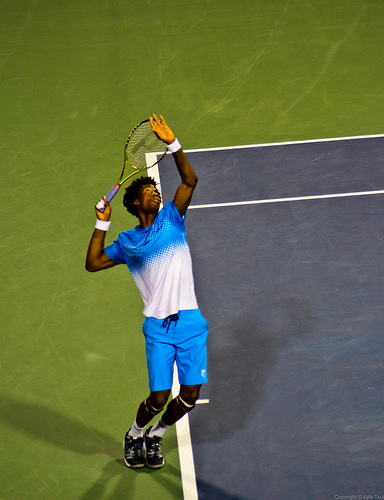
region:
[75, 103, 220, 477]
tennis player getting ready to serve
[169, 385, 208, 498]
white line discerning edge of tennis court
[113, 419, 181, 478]
tennis players feet with shoes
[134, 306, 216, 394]
tennis player with blue short on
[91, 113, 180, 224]
tennis racket getting ready to serve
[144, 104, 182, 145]
left hand of tennis player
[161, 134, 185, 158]
white wrist band on left arm of tennis player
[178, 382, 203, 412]
left knee of tennis player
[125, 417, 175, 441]
white socks of tennis player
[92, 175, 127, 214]
blue handle of tennis racket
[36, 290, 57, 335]
scuff marks on green tennis court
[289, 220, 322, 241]
scuff marks on blue tennis court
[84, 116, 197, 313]
man in blue and white shirt swinging racket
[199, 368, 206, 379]
white symbol on blue shorts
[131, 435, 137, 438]
yellow symbol on black shoes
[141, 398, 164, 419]
man wearing yellow and black knee pads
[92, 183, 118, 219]
man holding racket with blue handle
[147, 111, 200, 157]
tennis player wearing white sweatband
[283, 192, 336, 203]
white line on blue tennis court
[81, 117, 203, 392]
man in blue shorts swinging racket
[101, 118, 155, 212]
racquet held in right hand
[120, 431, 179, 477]
feet are together on court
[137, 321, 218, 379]
person wearing blue shorts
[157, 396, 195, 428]
sock is black and gold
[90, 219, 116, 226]
white wrist band on right wrist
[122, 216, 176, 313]
person wearing blue and white shirt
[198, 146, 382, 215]
white lines on the court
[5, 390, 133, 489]
shadow on the ground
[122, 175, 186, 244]
person looking up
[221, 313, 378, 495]
court is made of clay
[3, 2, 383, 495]
surface of tennis court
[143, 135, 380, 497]
blue section of court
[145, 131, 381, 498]
white lines on court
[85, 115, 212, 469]
tennis player on court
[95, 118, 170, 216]
racket in player's hand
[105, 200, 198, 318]
blue and white shirt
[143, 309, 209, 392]
blue shorts with strings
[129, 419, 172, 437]
white socks on feet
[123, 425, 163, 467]
shoes on two feet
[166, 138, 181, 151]
white band on wrist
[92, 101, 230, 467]
a man swinging a tennis racket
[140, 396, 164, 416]
a black and white knee support band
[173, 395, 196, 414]
a black and white knee support band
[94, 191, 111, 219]
a hand gripping a racket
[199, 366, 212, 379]
a white logo on shorts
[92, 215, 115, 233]
a white band on a wrist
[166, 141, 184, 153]
a white band on a wrist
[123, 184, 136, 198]
curly black hair on a head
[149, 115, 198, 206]
a hand reaching into the air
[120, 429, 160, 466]
black and blue sneakers